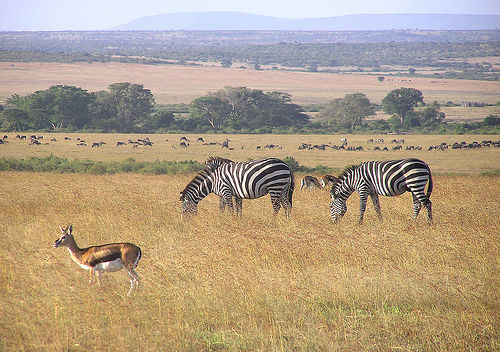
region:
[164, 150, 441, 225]
two grazing zebra in brush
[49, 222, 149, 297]
antelope with white belly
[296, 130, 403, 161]
herd of animals in the distance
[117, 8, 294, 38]
hazy mountain on the horizon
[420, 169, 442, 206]
tail on back of zebra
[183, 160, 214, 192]
mane on zebra neck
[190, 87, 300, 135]
trees beyond herd of animals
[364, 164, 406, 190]
stripes on zebra torso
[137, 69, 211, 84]
grass with no trees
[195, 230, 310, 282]
tall brown dried grass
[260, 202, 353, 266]
part of some dry grass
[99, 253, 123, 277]
stomach of a deer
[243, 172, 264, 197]
stomach of a zebra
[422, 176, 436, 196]
tail of a zebra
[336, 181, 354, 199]
neck of a zebra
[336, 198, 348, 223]
jaw of a zebra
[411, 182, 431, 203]
part of a thigh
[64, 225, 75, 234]
ear of a deer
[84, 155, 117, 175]
part of some green bush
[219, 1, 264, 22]
part of some hills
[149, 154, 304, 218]
this is a zebra feeding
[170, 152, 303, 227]
the zebra is white and black in color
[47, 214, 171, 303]
this is a gazelle beside the zebra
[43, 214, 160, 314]
the gazelle is brown and white in color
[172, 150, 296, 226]
the zebra is fat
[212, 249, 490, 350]
the grass is long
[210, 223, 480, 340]
the grass is brown in color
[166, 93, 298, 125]
trees are far on the photo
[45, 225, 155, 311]
the gazelle is small in size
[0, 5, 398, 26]
the sky is blue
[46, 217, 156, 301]
this is a antelope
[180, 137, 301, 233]
this is the left zebra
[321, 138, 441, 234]
this is the right zebra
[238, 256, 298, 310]
dead brown weeds and grass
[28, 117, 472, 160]
a large herd of animals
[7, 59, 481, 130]
the savannah in the disance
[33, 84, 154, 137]
this is a forest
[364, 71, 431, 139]
a single green tree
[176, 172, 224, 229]
a zebra head with stripes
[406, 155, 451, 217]
a black zebra tail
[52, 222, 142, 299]
Deer on a field.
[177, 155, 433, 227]
Two black and white zebras.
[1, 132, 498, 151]
Herd of animals grazing.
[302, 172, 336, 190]
Two deer standing in a field.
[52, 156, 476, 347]
Five animals in the field.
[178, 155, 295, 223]
Zebra grazing on brown grass.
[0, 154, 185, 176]
Green bushes dividing the pasture.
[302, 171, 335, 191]
Two deer eating grass.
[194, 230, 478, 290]
Brown grass and weeds.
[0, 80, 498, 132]
Green trees in the middle of open fields.